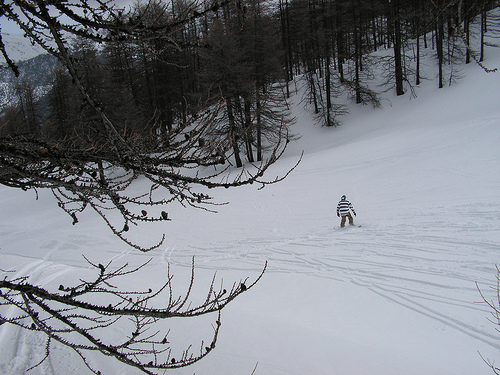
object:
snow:
[288, 256, 456, 347]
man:
[336, 195, 356, 227]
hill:
[0, 0, 497, 375]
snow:
[0, 22, 53, 104]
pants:
[341, 212, 354, 228]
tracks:
[209, 203, 500, 351]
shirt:
[336, 200, 356, 215]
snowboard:
[333, 225, 362, 230]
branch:
[0, 253, 268, 374]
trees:
[0, 0, 499, 167]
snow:
[366, 129, 483, 186]